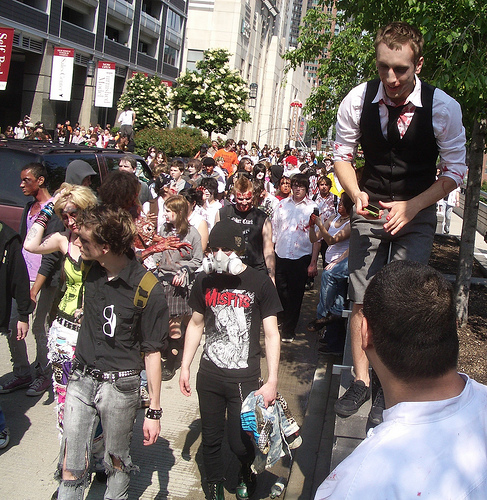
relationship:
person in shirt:
[261, 170, 336, 343] [270, 192, 317, 257]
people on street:
[1, 115, 352, 497] [1, 253, 348, 497]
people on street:
[176, 219, 282, 497] [1, 253, 348, 497]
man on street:
[57, 203, 173, 496] [1, 253, 348, 497]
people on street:
[21, 185, 99, 497] [1, 253, 348, 497]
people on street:
[149, 190, 204, 380] [1, 253, 348, 497]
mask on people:
[192, 206, 237, 285] [178, 219, 285, 497]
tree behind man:
[274, 1, 485, 298] [299, 20, 459, 426]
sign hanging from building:
[9, 47, 145, 120] [0, 1, 190, 132]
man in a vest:
[337, 37, 467, 414] [358, 77, 437, 208]